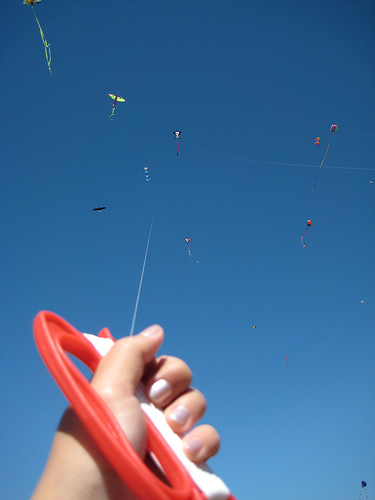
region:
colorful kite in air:
[84, 191, 114, 219]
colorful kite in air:
[132, 154, 164, 189]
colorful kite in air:
[173, 227, 209, 270]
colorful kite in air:
[284, 210, 326, 249]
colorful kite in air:
[349, 475, 373, 493]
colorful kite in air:
[309, 132, 322, 149]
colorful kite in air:
[309, 115, 343, 171]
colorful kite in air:
[156, 121, 195, 168]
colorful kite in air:
[97, 80, 129, 133]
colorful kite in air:
[16, 1, 67, 74]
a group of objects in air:
[77, 80, 370, 301]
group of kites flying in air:
[19, 13, 374, 311]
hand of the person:
[53, 319, 250, 493]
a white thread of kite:
[117, 208, 153, 360]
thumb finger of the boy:
[85, 324, 166, 387]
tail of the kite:
[24, 22, 64, 85]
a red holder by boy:
[30, 299, 153, 497]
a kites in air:
[285, 92, 358, 308]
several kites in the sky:
[47, 51, 371, 264]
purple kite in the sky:
[350, 471, 370, 497]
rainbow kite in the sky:
[292, 213, 318, 251]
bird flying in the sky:
[88, 198, 105, 215]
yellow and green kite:
[100, 83, 131, 118]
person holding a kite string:
[42, 284, 231, 493]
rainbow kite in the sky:
[309, 123, 323, 157]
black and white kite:
[169, 119, 184, 160]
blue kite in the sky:
[139, 161, 158, 192]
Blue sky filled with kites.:
[56, 105, 345, 245]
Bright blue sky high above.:
[234, 310, 317, 410]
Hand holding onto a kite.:
[32, 304, 230, 484]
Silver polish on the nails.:
[126, 363, 198, 425]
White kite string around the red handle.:
[147, 385, 235, 498]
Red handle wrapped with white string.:
[33, 296, 226, 492]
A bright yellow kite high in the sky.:
[96, 88, 132, 126]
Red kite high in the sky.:
[290, 211, 325, 255]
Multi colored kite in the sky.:
[136, 154, 159, 196]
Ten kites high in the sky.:
[21, 90, 348, 271]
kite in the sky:
[169, 128, 190, 154]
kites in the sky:
[66, 132, 212, 256]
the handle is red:
[106, 443, 136, 473]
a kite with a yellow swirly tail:
[105, 90, 127, 123]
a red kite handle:
[30, 308, 234, 499]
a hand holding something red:
[22, 321, 221, 499]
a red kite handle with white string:
[29, 310, 234, 499]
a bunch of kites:
[21, 1, 338, 244]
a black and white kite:
[172, 129, 182, 157]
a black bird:
[93, 205, 106, 211]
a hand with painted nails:
[23, 322, 222, 498]